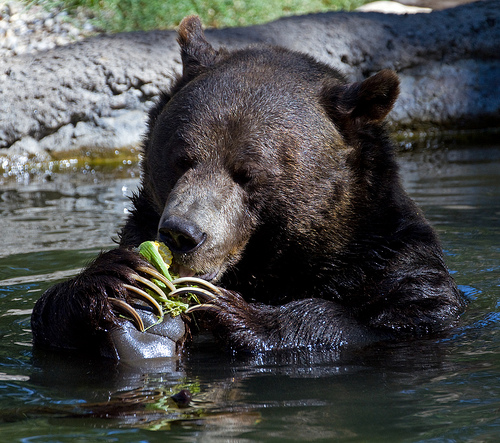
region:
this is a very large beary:
[36, 7, 498, 437]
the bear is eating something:
[83, 165, 278, 432]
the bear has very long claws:
[92, 225, 228, 345]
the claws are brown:
[103, 250, 224, 345]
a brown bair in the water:
[2, 12, 479, 397]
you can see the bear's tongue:
[167, 251, 210, 291]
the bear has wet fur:
[4, 15, 495, 430]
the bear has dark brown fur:
[0, 8, 497, 416]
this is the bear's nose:
[141, 190, 213, 262]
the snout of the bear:
[155, 175, 269, 319]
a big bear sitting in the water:
[41, 28, 466, 367]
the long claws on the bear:
[110, 261, 217, 336]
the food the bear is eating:
[123, 229, 191, 313]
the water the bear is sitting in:
[3, 158, 495, 441]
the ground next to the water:
[8, 15, 498, 142]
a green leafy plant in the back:
[41, 0, 351, 34]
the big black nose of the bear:
[156, 217, 207, 254]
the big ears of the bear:
[173, 11, 413, 124]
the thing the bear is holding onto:
[99, 260, 189, 364]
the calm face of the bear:
[145, 131, 287, 289]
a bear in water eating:
[40, 12, 477, 390]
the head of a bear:
[127, 12, 407, 284]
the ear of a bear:
[341, 57, 403, 136]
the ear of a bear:
[171, 14, 215, 74]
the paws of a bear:
[63, 253, 260, 360]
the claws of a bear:
[121, 272, 171, 331]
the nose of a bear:
[151, 215, 211, 250]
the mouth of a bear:
[193, 249, 232, 299]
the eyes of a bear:
[173, 151, 255, 190]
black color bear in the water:
[117, 46, 436, 392]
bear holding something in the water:
[64, 55, 486, 411]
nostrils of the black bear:
[156, 210, 209, 252]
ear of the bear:
[169, 10, 405, 117]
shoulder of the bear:
[353, 207, 460, 332]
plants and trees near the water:
[134, 5, 276, 20]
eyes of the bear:
[173, 128, 295, 200]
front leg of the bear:
[241, 277, 456, 369]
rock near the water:
[30, 27, 115, 167]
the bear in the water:
[23, 31, 433, 436]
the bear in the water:
[48, 27, 448, 412]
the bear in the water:
[63, 65, 411, 420]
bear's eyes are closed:
[125, 132, 307, 237]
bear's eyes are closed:
[125, 119, 323, 256]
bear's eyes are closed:
[120, 106, 312, 251]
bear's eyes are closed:
[118, 115, 337, 247]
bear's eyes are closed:
[127, 110, 309, 242]